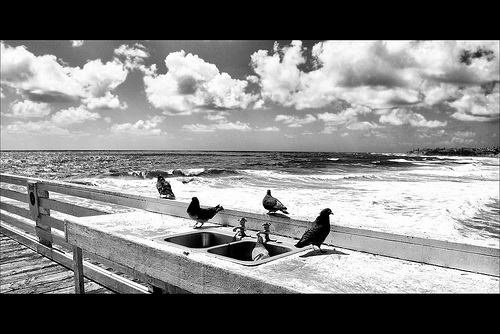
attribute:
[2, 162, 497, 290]
railings — horizontal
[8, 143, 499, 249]
ocean — black, white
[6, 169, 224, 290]
fence — wooden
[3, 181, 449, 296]
fence — wooden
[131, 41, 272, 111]
sky — blue 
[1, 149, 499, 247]
water — choppy, rough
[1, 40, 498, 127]
white clouds — white 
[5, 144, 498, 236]
water — choppy, foamy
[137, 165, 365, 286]
bird — dark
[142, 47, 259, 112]
clouds — white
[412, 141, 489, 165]
rocky area — rocky 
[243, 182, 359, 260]
bird — dark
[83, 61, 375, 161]
sky — blue 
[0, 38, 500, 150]
clouds — white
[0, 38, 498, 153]
sky — blue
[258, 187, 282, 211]
bird — resting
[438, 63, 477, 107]
cloud — white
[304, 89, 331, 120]
cloud — white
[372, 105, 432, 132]
cloud — white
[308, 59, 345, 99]
cloud — white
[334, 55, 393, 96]
cloud — white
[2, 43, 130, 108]
clouds — white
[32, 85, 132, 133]
clouds — white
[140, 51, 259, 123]
clouds — white 